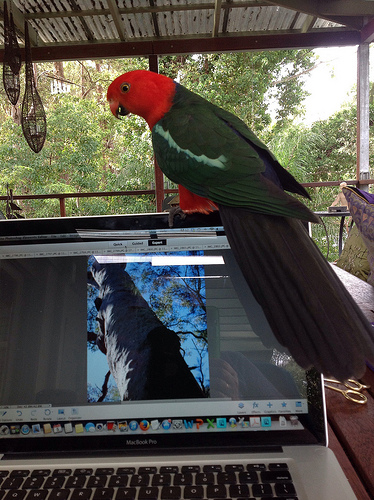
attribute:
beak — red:
[99, 99, 140, 129]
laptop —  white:
[3, 212, 359, 497]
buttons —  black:
[174, 437, 218, 490]